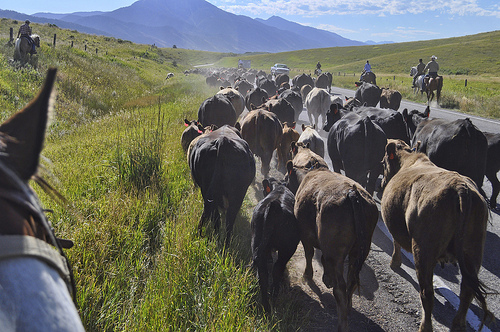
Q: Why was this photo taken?
A: To show the cattle.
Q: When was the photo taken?
A: During the day.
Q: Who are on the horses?
A: Farmers.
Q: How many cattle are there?
A: Many.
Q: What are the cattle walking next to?
A: The road.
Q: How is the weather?
A: Sunny.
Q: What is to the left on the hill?
A: A fence.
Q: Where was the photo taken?
A: Outside along the road.